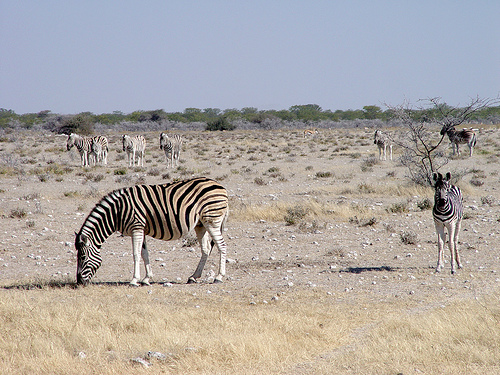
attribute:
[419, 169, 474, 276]
zebra — standing, here, young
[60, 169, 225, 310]
zebra — grazing, here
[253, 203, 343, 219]
grass — dead, tan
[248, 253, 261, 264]
rock — white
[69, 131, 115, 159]
zebras — standing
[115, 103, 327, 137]
trees — green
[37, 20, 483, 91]
skies — blue, clear, overcast, blue-gray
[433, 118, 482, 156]
zebra — here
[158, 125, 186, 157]
zebra — here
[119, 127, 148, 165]
zebra — here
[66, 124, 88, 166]
zebra — here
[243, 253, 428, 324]
ground — dry, gray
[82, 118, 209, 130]
bushes — gray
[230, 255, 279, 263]
stones — white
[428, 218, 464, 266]
legs — pale